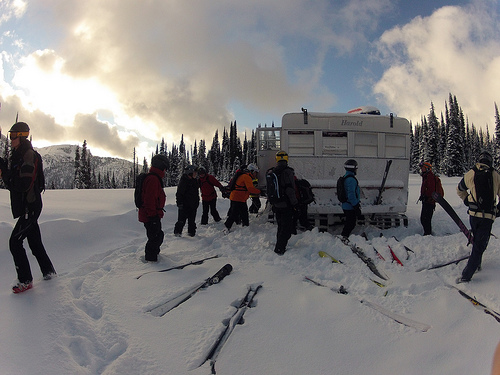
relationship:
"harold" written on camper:
[335, 115, 367, 129] [253, 106, 418, 230]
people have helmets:
[134, 153, 168, 261] [150, 153, 171, 169]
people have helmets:
[176, 165, 197, 235] [182, 163, 196, 173]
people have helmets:
[199, 164, 219, 223] [196, 164, 206, 172]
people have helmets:
[230, 162, 258, 227] [245, 164, 259, 173]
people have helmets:
[267, 149, 297, 254] [275, 150, 290, 162]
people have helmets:
[417, 162, 442, 236] [418, 160, 433, 172]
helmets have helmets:
[275, 150, 290, 162] [477, 150, 490, 162]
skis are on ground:
[135, 257, 270, 374] [4, 172, 494, 373]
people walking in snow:
[197, 166, 224, 225] [233, 223, 277, 272]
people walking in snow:
[174, 166, 200, 238] [233, 223, 277, 272]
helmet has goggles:
[9, 121, 30, 138] [7, 133, 22, 138]